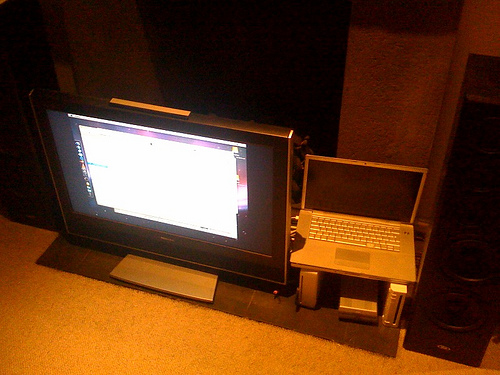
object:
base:
[108, 253, 221, 303]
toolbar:
[76, 140, 95, 200]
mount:
[297, 268, 410, 330]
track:
[336, 277, 378, 325]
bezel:
[106, 249, 220, 305]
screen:
[46, 111, 273, 267]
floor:
[0, 215, 499, 374]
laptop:
[291, 153, 428, 286]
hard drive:
[381, 282, 407, 327]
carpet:
[0, 221, 499, 375]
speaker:
[402, 51, 496, 368]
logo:
[439, 345, 450, 352]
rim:
[27, 84, 306, 289]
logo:
[160, 236, 175, 242]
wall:
[354, 52, 435, 158]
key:
[335, 237, 366, 247]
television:
[29, 90, 294, 304]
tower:
[401, 53, 498, 368]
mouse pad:
[333, 248, 373, 265]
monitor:
[45, 108, 273, 261]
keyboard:
[307, 210, 399, 255]